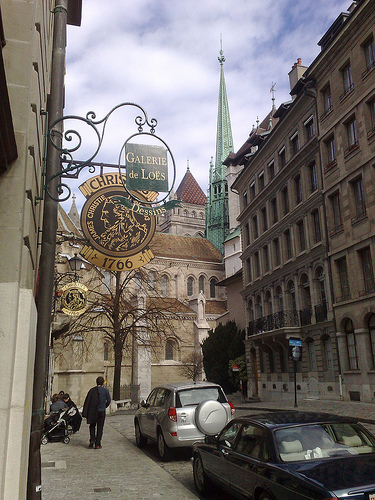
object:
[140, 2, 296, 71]
v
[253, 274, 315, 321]
window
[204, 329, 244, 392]
bushes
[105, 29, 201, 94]
clouds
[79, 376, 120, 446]
man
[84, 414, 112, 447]
pants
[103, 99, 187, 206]
metal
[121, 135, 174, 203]
sign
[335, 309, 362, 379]
window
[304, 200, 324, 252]
window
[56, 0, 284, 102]
clouds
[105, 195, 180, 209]
whiskers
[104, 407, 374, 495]
street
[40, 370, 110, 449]
stroller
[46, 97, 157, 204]
brace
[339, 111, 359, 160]
window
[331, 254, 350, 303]
window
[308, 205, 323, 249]
window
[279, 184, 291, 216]
window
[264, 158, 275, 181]
window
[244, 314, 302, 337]
fence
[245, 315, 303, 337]
balcony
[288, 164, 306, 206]
window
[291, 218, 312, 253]
window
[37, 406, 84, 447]
carriege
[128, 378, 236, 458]
car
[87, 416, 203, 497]
sidewalk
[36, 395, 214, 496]
sidewalk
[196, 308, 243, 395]
bush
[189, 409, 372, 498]
car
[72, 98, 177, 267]
sign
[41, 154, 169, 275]
banner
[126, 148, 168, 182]
lettering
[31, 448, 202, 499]
sidewalk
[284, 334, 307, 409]
signal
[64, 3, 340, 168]
sky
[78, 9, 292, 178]
sky